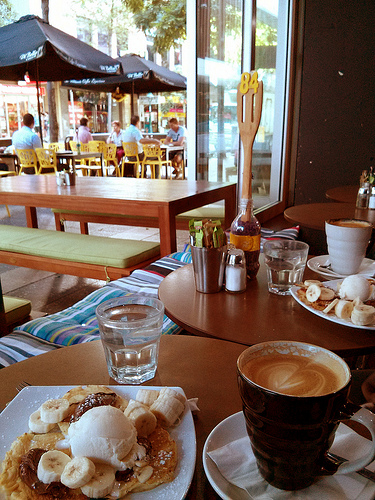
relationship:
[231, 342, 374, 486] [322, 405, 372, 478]
coffee mug with handle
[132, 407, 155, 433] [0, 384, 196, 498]
banana slice on plate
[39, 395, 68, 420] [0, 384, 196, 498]
banana slice on plate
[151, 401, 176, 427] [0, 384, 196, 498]
banana slice on plate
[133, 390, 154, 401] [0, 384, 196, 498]
banana slice on plate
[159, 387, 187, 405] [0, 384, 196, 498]
banana slice on plate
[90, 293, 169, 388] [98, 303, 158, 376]
glass filled with water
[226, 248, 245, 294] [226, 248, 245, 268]
salt shaker with metal lid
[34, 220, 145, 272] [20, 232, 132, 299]
cushion on bench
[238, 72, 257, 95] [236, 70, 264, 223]
table number on spatula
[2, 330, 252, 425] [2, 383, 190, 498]
plate of dessert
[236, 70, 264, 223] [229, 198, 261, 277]
spatula in jar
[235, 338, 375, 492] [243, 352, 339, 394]
coffee mug of beverage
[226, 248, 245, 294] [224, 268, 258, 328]
salt shaker on table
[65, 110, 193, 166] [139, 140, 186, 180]
people sitting at table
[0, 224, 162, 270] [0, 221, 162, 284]
cushion on bench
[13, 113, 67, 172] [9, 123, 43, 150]
man wearing a shirt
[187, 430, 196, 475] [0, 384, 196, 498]
edge on plate